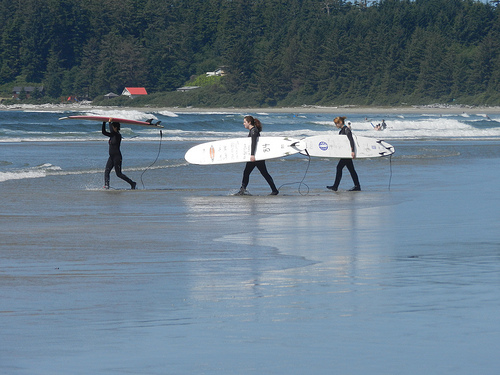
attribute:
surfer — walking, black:
[101, 118, 138, 190]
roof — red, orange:
[123, 85, 147, 96]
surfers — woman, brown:
[243, 114, 263, 135]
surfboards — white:
[185, 135, 308, 165]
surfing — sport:
[0, 111, 499, 198]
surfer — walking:
[235, 116, 278, 202]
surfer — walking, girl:
[327, 114, 362, 193]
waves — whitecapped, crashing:
[400, 116, 499, 140]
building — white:
[206, 68, 225, 80]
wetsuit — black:
[236, 129, 280, 200]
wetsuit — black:
[327, 126, 362, 192]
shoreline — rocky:
[1, 101, 162, 113]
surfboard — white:
[297, 133, 396, 159]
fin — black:
[145, 116, 162, 127]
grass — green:
[95, 96, 499, 106]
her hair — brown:
[334, 115, 346, 127]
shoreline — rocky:
[0, 102, 499, 114]